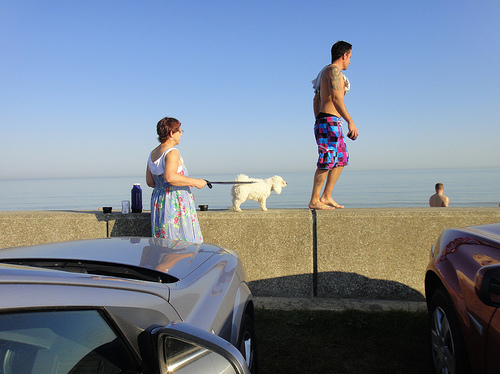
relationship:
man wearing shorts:
[309, 41, 357, 208] [315, 113, 348, 170]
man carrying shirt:
[309, 41, 357, 208] [313, 69, 349, 94]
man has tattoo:
[309, 41, 357, 208] [328, 68, 344, 93]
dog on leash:
[231, 174, 287, 211] [204, 177, 257, 189]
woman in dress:
[146, 115, 203, 245] [149, 146, 204, 244]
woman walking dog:
[146, 115, 203, 245] [231, 174, 287, 211]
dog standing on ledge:
[231, 174, 287, 211] [195, 210, 314, 295]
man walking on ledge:
[309, 41, 357, 208] [313, 210, 499, 300]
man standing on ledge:
[309, 41, 357, 208] [313, 210, 499, 300]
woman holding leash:
[146, 115, 203, 245] [204, 177, 257, 189]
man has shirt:
[309, 41, 357, 208] [313, 69, 349, 94]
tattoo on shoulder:
[328, 68, 344, 93] [313, 65, 344, 91]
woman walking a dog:
[146, 115, 203, 245] [231, 174, 287, 211]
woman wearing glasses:
[146, 115, 203, 245] [175, 127, 184, 136]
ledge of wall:
[313, 210, 499, 300] [3, 205, 499, 298]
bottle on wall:
[133, 187, 142, 213] [3, 205, 499, 298]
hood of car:
[2, 234, 224, 281] [0, 236, 254, 374]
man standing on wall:
[309, 41, 357, 208] [3, 205, 499, 298]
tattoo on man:
[328, 68, 344, 93] [309, 41, 357, 208]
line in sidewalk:
[328, 297, 340, 327] [253, 295, 428, 326]